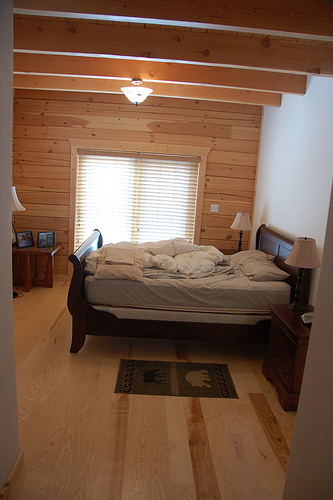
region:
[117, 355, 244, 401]
throw rug with a white bear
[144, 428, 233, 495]
natural wooden floor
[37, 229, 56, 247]
framed photograph of friends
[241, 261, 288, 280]
pillow with indent of head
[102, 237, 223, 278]
crumpled and disheveled heavy blanket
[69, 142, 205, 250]
closed white blinds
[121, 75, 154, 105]
powered on ceiling light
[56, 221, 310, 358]
large unmade unoccupied bed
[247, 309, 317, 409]
dark wooden bedside table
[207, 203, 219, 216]
white lightswitch panel set in wooden wall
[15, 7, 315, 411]
a bedroom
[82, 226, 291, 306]
an unmade bed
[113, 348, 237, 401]
a green rug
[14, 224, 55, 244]
two black picture frames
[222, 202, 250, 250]
white lamp on a night table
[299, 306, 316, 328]
a silver phone a night table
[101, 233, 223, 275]
a bed with rumpled white bedding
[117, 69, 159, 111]
a white ceiling lamp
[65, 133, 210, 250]
a window with white blinds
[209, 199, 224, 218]
a white light switch on a wood wall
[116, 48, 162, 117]
a ceiling light.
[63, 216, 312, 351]
a sleigh style bed.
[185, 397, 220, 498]
a brown board on the floor.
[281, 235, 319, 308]
a lamp on a table.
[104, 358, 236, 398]
a rug on a floor.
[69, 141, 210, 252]
a window in a room.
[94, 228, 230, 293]
a blanket on a bed.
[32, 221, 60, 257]
a picture in a frame.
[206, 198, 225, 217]
a light switch.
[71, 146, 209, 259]
mini blinds on a window.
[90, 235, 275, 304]
this is a bed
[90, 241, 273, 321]
the bed is full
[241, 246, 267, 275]
these are two pillows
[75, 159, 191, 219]
the window is closed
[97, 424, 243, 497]
the floor is wooden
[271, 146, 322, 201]
the wall is white in color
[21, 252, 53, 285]
the stool is wooden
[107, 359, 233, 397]
this is a mat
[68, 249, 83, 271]
the bed is wooden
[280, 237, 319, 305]
this is a lampstand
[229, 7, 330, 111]
four wooden beams on the ceiling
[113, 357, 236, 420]
rug next to bed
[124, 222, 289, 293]
the bed has not been made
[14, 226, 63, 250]
picture frames on the table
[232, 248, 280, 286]
two pillows on the bed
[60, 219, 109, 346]
footboard of the bed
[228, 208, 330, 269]
two lamps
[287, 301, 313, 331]
telephone on nightstand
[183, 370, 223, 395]
white bear on the rug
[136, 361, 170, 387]
black moose on the rug